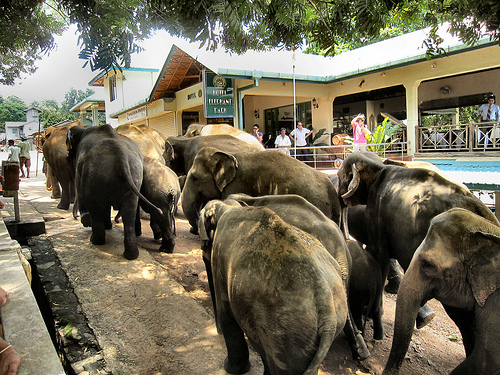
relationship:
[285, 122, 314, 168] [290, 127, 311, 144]
man wearing shirt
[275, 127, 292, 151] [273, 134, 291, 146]
man wearing shirt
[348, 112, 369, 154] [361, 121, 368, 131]
person with hand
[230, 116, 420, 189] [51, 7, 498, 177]
people standing at station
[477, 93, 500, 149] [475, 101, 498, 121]
man in shirt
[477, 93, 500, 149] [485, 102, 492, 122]
man in tie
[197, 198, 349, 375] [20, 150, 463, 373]
elehant walking down street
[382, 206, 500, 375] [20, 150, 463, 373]
elehant walking down street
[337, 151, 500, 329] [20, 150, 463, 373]
elehant walking down street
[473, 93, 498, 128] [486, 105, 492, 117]
man wearing tie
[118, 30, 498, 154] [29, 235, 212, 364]
hotel next to street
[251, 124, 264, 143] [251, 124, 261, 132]
people talking on cell phone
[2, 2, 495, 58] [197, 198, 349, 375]
branches above elehant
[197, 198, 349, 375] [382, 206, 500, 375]
elehant an elehant